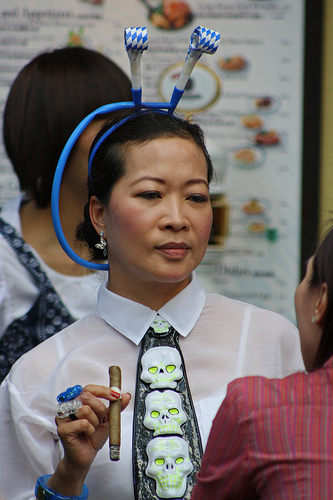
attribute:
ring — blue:
[37, 385, 84, 406]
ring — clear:
[51, 405, 90, 416]